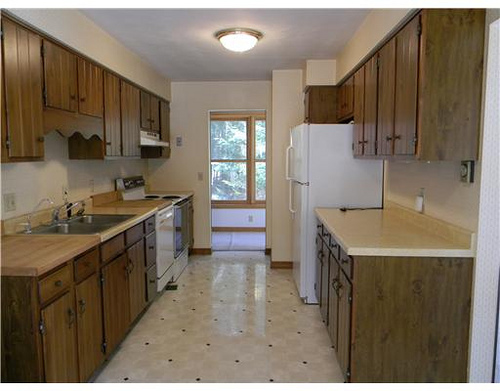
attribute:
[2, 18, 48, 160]
cabinet — brown, wooden, made of wood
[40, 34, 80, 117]
cabinet — brown, wooden, made of wood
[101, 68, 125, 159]
cabinet — brown, wooden, made of wood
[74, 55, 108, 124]
cabinet — brown, wooden, made of wood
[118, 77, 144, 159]
cabinet — brown, wooden, made of wood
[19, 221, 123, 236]
sink — chrome, silver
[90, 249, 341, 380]
floor tile — black, white, brown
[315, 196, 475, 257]
countertop — beige, yellowish, ceramic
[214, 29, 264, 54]
light — on, round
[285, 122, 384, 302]
refrigerator — white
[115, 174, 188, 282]
stove — white, black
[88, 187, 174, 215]
countertop — yellowish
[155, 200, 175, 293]
dishwasher — white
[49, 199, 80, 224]
faucet — silver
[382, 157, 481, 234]
wall — tan, white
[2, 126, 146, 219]
wall — white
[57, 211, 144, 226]
sink — silver